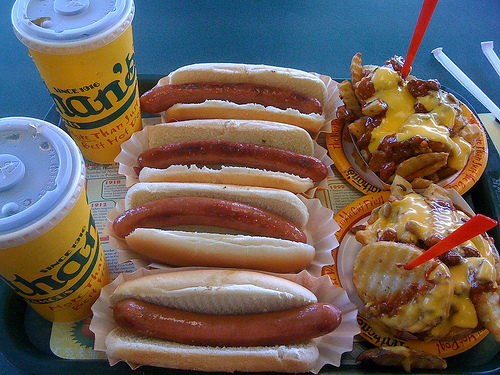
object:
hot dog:
[139, 81, 325, 117]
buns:
[161, 63, 327, 134]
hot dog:
[136, 141, 329, 182]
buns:
[136, 119, 317, 193]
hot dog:
[111, 194, 308, 245]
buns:
[121, 181, 313, 274]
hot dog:
[113, 297, 342, 348]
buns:
[105, 268, 318, 373]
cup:
[8, 0, 144, 164]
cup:
[0, 116, 113, 326]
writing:
[93, 80, 126, 111]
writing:
[56, 248, 89, 282]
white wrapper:
[149, 63, 345, 141]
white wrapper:
[114, 123, 335, 199]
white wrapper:
[104, 189, 338, 278]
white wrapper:
[87, 267, 362, 374]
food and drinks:
[0, 0, 500, 375]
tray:
[2, 73, 500, 375]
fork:
[400, 0, 440, 81]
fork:
[402, 214, 497, 273]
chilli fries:
[361, 65, 393, 117]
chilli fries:
[351, 241, 455, 334]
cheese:
[387, 88, 410, 120]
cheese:
[402, 206, 424, 224]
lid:
[11, 0, 134, 54]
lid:
[1, 113, 88, 250]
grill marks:
[173, 84, 221, 89]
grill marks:
[179, 145, 219, 155]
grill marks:
[134, 208, 185, 228]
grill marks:
[121, 314, 169, 340]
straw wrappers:
[474, 112, 500, 155]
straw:
[429, 45, 500, 120]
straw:
[479, 40, 500, 80]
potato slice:
[351, 240, 453, 334]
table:
[1, 2, 499, 374]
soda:
[34, 16, 49, 28]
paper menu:
[45, 114, 410, 364]